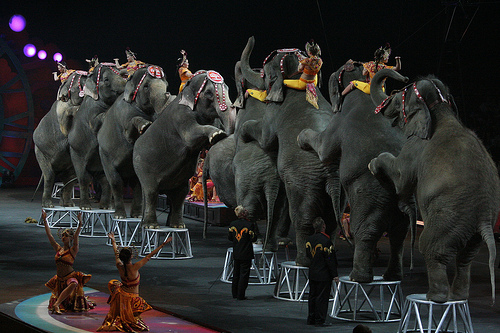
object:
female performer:
[93, 230, 173, 333]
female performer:
[39, 208, 97, 315]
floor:
[0, 183, 495, 332]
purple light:
[7, 13, 27, 34]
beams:
[333, 284, 355, 318]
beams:
[359, 284, 381, 321]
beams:
[384, 283, 399, 321]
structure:
[327, 275, 406, 323]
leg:
[424, 261, 451, 294]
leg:
[103, 166, 127, 212]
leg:
[37, 161, 57, 200]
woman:
[281, 41, 325, 109]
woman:
[339, 41, 402, 97]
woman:
[174, 48, 194, 94]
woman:
[112, 48, 147, 81]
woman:
[51, 59, 88, 85]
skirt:
[43, 269, 98, 315]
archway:
[0, 57, 38, 187]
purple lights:
[21, 43, 36, 58]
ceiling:
[2, 0, 499, 53]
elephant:
[366, 64, 500, 305]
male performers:
[303, 215, 340, 327]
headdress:
[187, 69, 227, 112]